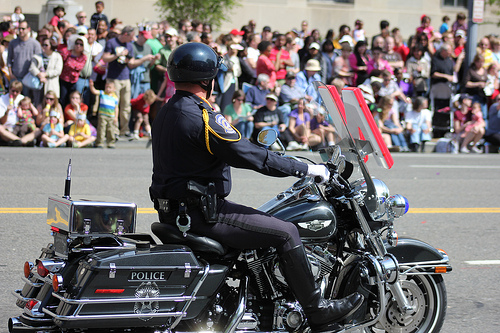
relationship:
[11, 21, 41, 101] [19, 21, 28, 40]
man has a head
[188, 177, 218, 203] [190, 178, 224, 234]
gun inside holster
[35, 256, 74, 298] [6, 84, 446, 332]
signal on back of motorcycle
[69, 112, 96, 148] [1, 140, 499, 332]
boy sitting on street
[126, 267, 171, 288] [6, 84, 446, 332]
police written on motorcycle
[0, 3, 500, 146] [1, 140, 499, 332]
crowd beside street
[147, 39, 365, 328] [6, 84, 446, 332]
officer riding motorcycle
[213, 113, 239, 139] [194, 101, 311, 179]
emblem attached to sleeve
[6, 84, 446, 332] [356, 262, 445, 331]
motorcycle has a tire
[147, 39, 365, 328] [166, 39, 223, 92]
officer wearing helmet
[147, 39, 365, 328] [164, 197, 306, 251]
officer wearing pants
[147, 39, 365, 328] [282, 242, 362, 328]
officer wearing boot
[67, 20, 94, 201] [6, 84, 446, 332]
antenna attached to motorcycle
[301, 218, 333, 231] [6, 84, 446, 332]
logo on side of motorcycle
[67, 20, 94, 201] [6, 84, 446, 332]
antenna on back of motorcycle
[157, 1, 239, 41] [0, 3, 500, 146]
tree behind crowd